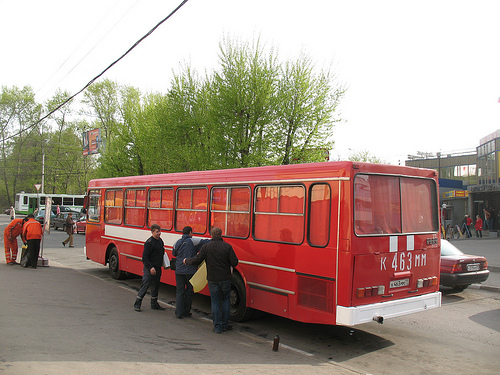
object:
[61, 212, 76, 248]
walking man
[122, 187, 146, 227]
window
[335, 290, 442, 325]
white bumper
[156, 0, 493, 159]
cloud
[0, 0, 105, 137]
cloud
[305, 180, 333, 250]
window bus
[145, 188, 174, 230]
window bus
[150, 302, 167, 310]
shoe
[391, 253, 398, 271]
numbers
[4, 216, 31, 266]
man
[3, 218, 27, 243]
orange clothes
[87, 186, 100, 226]
window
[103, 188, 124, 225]
bus window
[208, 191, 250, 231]
window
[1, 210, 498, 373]
street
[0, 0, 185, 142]
line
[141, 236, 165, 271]
clothes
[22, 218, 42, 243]
jacket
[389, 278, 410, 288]
license plate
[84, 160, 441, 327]
bus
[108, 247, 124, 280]
tire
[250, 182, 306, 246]
window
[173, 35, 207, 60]
white clouds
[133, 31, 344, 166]
tree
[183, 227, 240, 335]
man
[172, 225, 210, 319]
man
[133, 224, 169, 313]
man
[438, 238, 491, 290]
car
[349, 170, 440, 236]
rear window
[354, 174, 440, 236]
curtains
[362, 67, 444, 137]
white clouds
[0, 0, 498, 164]
blue sky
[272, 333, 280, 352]
bottle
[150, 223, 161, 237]
head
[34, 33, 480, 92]
clouds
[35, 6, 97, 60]
clouds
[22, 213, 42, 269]
man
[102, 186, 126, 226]
window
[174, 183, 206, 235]
window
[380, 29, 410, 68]
cloud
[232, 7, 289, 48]
cloud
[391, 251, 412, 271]
number 463